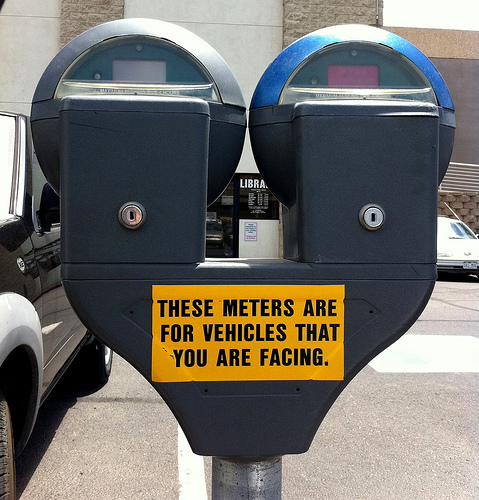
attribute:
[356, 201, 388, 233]
bolt — silver, white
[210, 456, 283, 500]
post — silver, gray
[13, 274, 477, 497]
sidewalk — painted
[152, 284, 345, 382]
sign — yellow, black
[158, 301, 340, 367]
wording — black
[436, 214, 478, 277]
car — white, parked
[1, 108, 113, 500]
car — black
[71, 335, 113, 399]
wheel — black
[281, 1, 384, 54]
wall — stone, gray, tan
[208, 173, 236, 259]
window — clear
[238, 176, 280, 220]
window — clear, black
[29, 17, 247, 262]
meter — gray, black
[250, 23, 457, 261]
meter — gray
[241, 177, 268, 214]
lettering — white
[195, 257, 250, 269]
sunlight — square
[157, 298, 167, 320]
letter t — black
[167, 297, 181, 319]
letter h — black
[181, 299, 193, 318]
letter e — black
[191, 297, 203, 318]
letter s — black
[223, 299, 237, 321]
letter m — black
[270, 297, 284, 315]
letter r — black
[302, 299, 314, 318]
letter a — black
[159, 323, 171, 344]
letter f — black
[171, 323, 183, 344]
letter o — black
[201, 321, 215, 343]
letter v — black